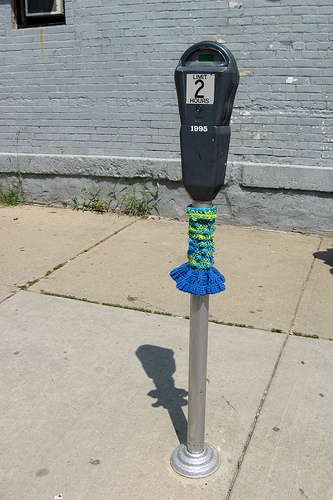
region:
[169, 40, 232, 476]
a marking meter with a knit scarf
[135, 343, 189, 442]
shadow of a parking meter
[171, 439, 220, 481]
metal base of a parking meter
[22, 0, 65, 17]
an air conditioning unit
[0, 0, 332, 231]
a grey brick building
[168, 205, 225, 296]
a knit scarf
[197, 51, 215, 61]
screen on a parking meter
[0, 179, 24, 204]
small weeds coming up through pavement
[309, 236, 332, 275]
shadow on pavement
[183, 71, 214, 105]
white and black sign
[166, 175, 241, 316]
the parking meter has a crocheted skirt on it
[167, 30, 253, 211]
a parking meter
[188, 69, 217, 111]
the limit of parking at this meter is 2 hours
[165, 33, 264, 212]
the meter is black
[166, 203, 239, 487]
the post is silvery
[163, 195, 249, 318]
the crocheted skirt is blue, green & yellow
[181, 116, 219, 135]
the number on the front of the meter is 1995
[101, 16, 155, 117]
the building is made of bricks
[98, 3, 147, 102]
the bricks are painted grey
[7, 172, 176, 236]
grass is growing out of the crack along the building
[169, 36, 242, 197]
a parking meter on a sidewalk.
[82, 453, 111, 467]
melted bubble gum.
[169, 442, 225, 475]
a foundation for a parking meter.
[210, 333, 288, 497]
a line in a sidewalk.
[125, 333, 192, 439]
a shadow cast by a parking meter.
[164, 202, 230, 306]
a dress on a parking meter.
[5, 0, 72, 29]
a window on the side of a building.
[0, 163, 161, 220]
grass growing out of a sidewalk crack.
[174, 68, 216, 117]
a number 2 sticker.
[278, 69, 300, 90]
damaged paint.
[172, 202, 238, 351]
knitted dress on meter pole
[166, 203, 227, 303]
knitted yellow and blue dress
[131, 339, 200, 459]
meter shadow on sidewalk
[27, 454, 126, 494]
dark spots on sidewalk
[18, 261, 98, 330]
grass growing between bricks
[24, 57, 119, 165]
light blue painted bricks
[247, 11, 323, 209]
old blue brick wall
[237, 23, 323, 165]
paint falling off brick wall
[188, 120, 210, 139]
1995 numbers on meter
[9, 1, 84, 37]
air conditioner sticking out of window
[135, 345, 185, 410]
shadow on the ground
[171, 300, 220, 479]
a metal pole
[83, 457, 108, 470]
spots on the ground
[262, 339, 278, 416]
a crack in the ground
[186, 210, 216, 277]
cloth on the pole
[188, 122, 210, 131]
white numbers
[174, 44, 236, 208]
a meter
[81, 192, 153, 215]
small grass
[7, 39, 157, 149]
a blue brick building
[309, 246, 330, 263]
a shadow